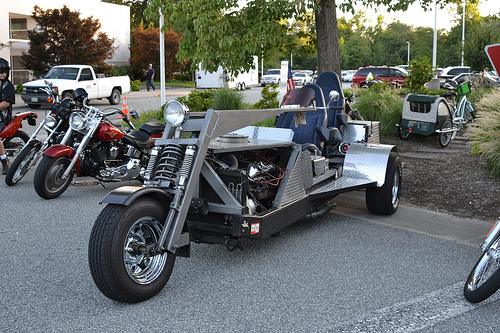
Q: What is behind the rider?
A: A buddy seat.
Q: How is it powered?
A: A gasoline engine.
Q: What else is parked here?
A: 5 more cycles.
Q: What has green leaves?
A: A tree nearby.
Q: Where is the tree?
A: Above a cycle.